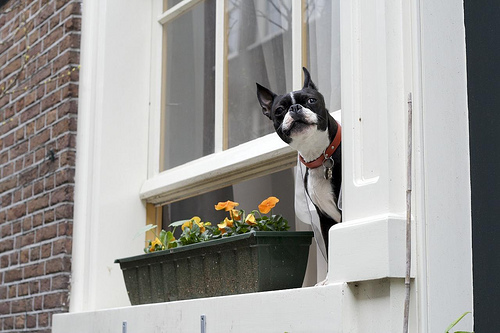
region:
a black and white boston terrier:
[254, 65, 343, 284]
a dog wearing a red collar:
[254, 65, 343, 285]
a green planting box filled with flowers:
[112, 196, 316, 309]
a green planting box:
[112, 229, 314, 304]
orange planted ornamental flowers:
[132, 196, 290, 254]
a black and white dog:
[254, 79, 354, 283]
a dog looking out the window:
[251, 76, 361, 284]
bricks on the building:
[1, 5, 72, 322]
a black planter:
[115, 223, 309, 298]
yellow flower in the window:
[157, 198, 299, 239]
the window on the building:
[153, 10, 328, 217]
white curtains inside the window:
[308, 52, 345, 110]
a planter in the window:
[116, 190, 303, 296]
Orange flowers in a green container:
[206, 191, 282, 273]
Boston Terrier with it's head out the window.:
[247, 68, 338, 205]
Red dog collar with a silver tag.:
[290, 128, 342, 184]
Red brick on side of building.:
[9, 125, 61, 258]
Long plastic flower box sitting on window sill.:
[98, 230, 305, 318]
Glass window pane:
[148, 39, 219, 176]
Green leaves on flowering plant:
[254, 212, 285, 228]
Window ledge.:
[70, 281, 368, 325]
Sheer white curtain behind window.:
[267, 0, 347, 285]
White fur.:
[295, 134, 322, 161]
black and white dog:
[252, 67, 342, 247]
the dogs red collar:
[293, 125, 343, 167]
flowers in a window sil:
[114, 196, 314, 292]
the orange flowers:
[218, 196, 276, 214]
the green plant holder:
[116, 229, 299, 289]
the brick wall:
[17, 78, 66, 210]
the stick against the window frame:
[401, 87, 411, 329]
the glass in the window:
[163, 18, 215, 151]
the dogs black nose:
[289, 105, 300, 112]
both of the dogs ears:
[252, 63, 325, 114]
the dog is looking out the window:
[199, 42, 374, 330]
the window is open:
[128, 92, 296, 316]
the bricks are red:
[4, 74, 34, 262]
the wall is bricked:
[7, 67, 69, 272]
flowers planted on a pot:
[92, 182, 300, 294]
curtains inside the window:
[145, 20, 252, 167]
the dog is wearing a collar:
[250, 134, 346, 183]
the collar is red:
[305, 148, 360, 202]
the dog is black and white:
[217, 60, 348, 181]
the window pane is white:
[113, 36, 338, 217]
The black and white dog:
[249, 66, 342, 289]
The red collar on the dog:
[295, 121, 340, 171]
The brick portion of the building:
[0, 0, 82, 332]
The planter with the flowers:
[111, 226, 313, 306]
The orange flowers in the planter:
[140, 194, 282, 252]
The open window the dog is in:
[140, 165, 324, 289]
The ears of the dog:
[253, 64, 317, 120]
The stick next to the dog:
[399, 78, 421, 331]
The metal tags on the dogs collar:
[319, 153, 338, 183]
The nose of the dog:
[285, 101, 303, 118]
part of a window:
[233, 31, 263, 73]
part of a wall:
[413, 235, 430, 282]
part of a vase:
[229, 260, 264, 300]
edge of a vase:
[190, 229, 227, 256]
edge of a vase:
[63, 187, 98, 259]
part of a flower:
[211, 191, 238, 223]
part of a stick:
[403, 246, 415, 285]